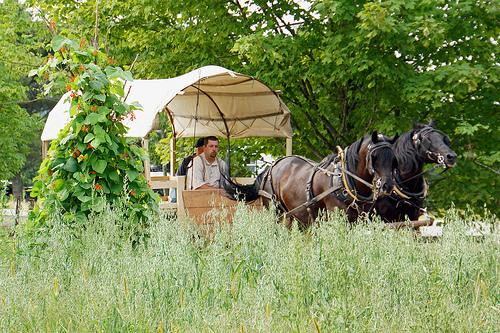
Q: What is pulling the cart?
A: Horse.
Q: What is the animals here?
A: Horses.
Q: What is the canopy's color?
A: White.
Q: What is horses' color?
A: Brown.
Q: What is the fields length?
A: Very tall.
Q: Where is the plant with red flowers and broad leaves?
A: To the left of the wagon.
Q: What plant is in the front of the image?
A: Tall grass.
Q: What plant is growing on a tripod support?
A: The one with red flowers.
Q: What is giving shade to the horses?
A: A canopy of green trees.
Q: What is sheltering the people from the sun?
A: A beige canopy.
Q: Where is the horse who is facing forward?
A: To the right.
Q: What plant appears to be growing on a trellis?
A: The one with orange flowers.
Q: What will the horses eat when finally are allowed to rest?
A: The tall grass.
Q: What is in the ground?
A: Grass.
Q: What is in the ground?
A: Trees.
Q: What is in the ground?
A: Passengers.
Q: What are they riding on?
A: Wagon.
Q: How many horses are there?
A: 2.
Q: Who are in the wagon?
A: Men.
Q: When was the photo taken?
A: Daytime.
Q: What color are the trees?
A: Green.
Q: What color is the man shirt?
A: White.